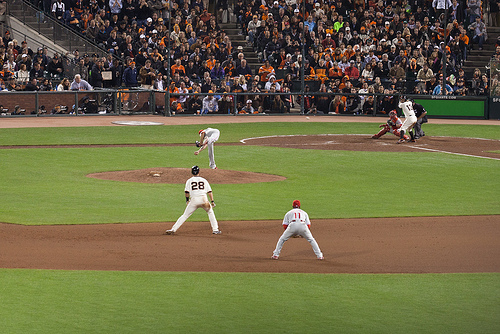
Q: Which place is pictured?
A: It is a field.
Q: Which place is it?
A: It is a field.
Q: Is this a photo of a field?
A: Yes, it is showing a field.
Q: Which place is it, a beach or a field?
A: It is a field.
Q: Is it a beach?
A: No, it is a field.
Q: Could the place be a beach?
A: No, it is a field.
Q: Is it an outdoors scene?
A: Yes, it is outdoors.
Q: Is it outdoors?
A: Yes, it is outdoors.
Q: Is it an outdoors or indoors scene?
A: It is outdoors.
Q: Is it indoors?
A: No, it is outdoors.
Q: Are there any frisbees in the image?
A: No, there are no frisbees.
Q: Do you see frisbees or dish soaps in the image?
A: No, there are no frisbees or dish soaps.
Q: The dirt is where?
A: The dirt is on the field.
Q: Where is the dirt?
A: The dirt is on the field.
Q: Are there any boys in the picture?
A: No, there are no boys.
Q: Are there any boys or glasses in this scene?
A: No, there are no boys or glasses.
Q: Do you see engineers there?
A: No, there are no engineers.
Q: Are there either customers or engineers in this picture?
A: No, there are no engineers or customers.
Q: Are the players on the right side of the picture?
A: Yes, the players are on the right of the image.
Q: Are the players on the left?
A: No, the players are on the right of the image.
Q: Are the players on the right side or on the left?
A: The players are on the right of the image.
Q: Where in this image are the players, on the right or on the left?
A: The players are on the right of the image.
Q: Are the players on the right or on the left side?
A: The players are on the right of the image.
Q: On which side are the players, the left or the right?
A: The players are on the right of the image.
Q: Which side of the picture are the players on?
A: The players are on the right of the image.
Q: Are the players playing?
A: Yes, the players are playing.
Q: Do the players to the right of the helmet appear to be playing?
A: Yes, the players are playing.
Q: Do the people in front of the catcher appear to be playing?
A: Yes, the players are playing.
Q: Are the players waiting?
A: No, the players are playing.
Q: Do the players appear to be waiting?
A: No, the players are playing.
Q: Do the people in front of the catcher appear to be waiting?
A: No, the players are playing.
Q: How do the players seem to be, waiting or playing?
A: The players are playing.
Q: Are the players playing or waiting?
A: The players are playing.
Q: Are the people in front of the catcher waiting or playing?
A: The players are playing.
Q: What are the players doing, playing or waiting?
A: The players are playing.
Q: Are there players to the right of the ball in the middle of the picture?
A: Yes, there are players to the right of the ball.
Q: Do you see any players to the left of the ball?
A: No, the players are to the right of the ball.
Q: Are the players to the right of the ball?
A: Yes, the players are to the right of the ball.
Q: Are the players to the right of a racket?
A: No, the players are to the right of the ball.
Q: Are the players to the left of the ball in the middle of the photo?
A: No, the players are to the right of the ball.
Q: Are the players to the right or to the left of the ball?
A: The players are to the right of the ball.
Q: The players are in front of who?
A: The players are in front of the catcher.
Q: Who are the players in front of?
A: The players are in front of the catcher.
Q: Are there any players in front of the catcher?
A: Yes, there are players in front of the catcher.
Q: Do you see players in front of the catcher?
A: Yes, there are players in front of the catcher.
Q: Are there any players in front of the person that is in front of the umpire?
A: Yes, there are players in front of the catcher.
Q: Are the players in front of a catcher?
A: Yes, the players are in front of a catcher.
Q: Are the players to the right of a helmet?
A: Yes, the players are to the right of a helmet.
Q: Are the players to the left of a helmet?
A: No, the players are to the right of a helmet.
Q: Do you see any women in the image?
A: No, there are no women.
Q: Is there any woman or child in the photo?
A: No, there are no women or children.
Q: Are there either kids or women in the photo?
A: No, there are no women or kids.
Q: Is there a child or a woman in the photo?
A: No, there are no women or children.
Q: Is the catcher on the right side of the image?
A: Yes, the catcher is on the right of the image.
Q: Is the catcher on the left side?
A: No, the catcher is on the right of the image.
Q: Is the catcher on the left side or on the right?
A: The catcher is on the right of the image.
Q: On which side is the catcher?
A: The catcher is on the right of the image.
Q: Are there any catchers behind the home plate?
A: Yes, there is a catcher behind the home plate.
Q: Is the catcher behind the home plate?
A: Yes, the catcher is behind the home plate.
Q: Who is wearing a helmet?
A: The catcher is wearing a helmet.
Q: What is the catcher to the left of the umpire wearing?
A: The catcher is wearing a helmet.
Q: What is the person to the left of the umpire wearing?
A: The catcher is wearing a helmet.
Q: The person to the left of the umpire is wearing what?
A: The catcher is wearing a helmet.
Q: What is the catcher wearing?
A: The catcher is wearing a helmet.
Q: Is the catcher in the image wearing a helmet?
A: Yes, the catcher is wearing a helmet.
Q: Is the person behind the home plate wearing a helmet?
A: Yes, the catcher is wearing a helmet.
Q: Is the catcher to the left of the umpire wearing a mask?
A: No, the catcher is wearing a helmet.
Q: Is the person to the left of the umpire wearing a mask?
A: No, the catcher is wearing a helmet.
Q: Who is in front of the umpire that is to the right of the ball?
A: The catcher is in front of the umpire.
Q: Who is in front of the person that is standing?
A: The catcher is in front of the umpire.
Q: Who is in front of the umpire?
A: The catcher is in front of the umpire.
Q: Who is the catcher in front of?
A: The catcher is in front of the umpire.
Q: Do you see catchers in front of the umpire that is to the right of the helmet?
A: Yes, there is a catcher in front of the umpire.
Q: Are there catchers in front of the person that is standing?
A: Yes, there is a catcher in front of the umpire.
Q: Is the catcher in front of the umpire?
A: Yes, the catcher is in front of the umpire.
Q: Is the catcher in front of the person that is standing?
A: Yes, the catcher is in front of the umpire.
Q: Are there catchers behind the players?
A: Yes, there is a catcher behind the players.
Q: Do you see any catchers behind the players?
A: Yes, there is a catcher behind the players.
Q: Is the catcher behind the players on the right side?
A: Yes, the catcher is behind the players.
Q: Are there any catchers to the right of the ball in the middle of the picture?
A: Yes, there is a catcher to the right of the ball.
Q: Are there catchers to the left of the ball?
A: No, the catcher is to the right of the ball.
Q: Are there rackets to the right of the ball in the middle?
A: No, there is a catcher to the right of the ball.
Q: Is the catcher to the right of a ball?
A: Yes, the catcher is to the right of a ball.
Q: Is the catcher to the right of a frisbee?
A: No, the catcher is to the right of a ball.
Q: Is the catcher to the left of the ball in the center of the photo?
A: No, the catcher is to the right of the ball.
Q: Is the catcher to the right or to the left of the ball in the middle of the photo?
A: The catcher is to the right of the ball.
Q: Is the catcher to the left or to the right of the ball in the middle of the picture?
A: The catcher is to the right of the ball.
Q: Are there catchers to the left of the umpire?
A: Yes, there is a catcher to the left of the umpire.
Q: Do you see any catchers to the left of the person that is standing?
A: Yes, there is a catcher to the left of the umpire.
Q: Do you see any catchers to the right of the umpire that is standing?
A: No, the catcher is to the left of the umpire.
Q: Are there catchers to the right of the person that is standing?
A: No, the catcher is to the left of the umpire.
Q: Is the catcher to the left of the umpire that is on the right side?
A: Yes, the catcher is to the left of the umpire.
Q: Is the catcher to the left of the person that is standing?
A: Yes, the catcher is to the left of the umpire.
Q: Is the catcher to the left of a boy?
A: No, the catcher is to the left of the umpire.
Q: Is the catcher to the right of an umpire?
A: No, the catcher is to the left of an umpire.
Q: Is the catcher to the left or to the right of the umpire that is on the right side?
A: The catcher is to the left of the umpire.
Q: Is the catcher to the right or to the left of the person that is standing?
A: The catcher is to the left of the umpire.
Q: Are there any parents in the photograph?
A: No, there are no parents.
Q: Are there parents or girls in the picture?
A: No, there are no parents or girls.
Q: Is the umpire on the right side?
A: Yes, the umpire is on the right of the image.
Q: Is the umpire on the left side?
A: No, the umpire is on the right of the image.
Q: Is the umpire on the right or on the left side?
A: The umpire is on the right of the image.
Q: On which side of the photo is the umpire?
A: The umpire is on the right of the image.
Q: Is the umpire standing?
A: Yes, the umpire is standing.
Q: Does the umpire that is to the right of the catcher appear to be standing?
A: Yes, the umpire is standing.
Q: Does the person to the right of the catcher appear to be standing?
A: Yes, the umpire is standing.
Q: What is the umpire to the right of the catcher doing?
A: The umpire is standing.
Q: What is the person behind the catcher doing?
A: The umpire is standing.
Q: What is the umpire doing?
A: The umpire is standing.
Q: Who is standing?
A: The umpire is standing.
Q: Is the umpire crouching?
A: No, the umpire is standing.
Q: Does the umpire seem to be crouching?
A: No, the umpire is standing.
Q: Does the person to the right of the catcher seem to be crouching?
A: No, the umpire is standing.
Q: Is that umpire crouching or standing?
A: The umpire is standing.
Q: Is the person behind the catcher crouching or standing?
A: The umpire is standing.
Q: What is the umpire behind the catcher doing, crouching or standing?
A: The umpire is standing.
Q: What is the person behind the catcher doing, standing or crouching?
A: The umpire is standing.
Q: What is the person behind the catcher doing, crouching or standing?
A: The umpire is standing.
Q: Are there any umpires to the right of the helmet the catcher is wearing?
A: Yes, there is an umpire to the right of the helmet.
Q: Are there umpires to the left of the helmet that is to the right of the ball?
A: No, the umpire is to the right of the helmet.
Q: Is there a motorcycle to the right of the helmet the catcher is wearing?
A: No, there is an umpire to the right of the helmet.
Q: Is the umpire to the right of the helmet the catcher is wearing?
A: Yes, the umpire is to the right of the helmet.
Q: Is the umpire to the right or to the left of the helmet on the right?
A: The umpire is to the right of the helmet.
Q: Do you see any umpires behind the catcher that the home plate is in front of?
A: Yes, there is an umpire behind the catcher.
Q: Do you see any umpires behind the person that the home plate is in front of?
A: Yes, there is an umpire behind the catcher.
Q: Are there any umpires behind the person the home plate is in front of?
A: Yes, there is an umpire behind the catcher.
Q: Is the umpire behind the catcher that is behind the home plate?
A: Yes, the umpire is behind the catcher.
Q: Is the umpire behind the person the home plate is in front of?
A: Yes, the umpire is behind the catcher.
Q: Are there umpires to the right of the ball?
A: Yes, there is an umpire to the right of the ball.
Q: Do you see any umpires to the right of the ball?
A: Yes, there is an umpire to the right of the ball.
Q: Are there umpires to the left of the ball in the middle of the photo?
A: No, the umpire is to the right of the ball.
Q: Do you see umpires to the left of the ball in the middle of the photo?
A: No, the umpire is to the right of the ball.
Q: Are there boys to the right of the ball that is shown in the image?
A: No, there is an umpire to the right of the ball.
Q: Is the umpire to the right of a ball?
A: Yes, the umpire is to the right of a ball.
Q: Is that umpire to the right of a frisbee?
A: No, the umpire is to the right of a ball.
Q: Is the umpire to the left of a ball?
A: No, the umpire is to the right of a ball.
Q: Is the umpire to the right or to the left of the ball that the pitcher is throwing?
A: The umpire is to the right of the ball.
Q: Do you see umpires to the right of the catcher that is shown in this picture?
A: Yes, there is an umpire to the right of the catcher.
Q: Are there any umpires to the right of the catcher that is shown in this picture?
A: Yes, there is an umpire to the right of the catcher.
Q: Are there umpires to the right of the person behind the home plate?
A: Yes, there is an umpire to the right of the catcher.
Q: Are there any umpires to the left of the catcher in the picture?
A: No, the umpire is to the right of the catcher.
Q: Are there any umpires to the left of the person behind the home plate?
A: No, the umpire is to the right of the catcher.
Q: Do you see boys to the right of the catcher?
A: No, there is an umpire to the right of the catcher.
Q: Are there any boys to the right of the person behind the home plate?
A: No, there is an umpire to the right of the catcher.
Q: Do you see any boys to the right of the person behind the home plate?
A: No, there is an umpire to the right of the catcher.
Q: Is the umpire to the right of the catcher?
A: Yes, the umpire is to the right of the catcher.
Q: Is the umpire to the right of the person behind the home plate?
A: Yes, the umpire is to the right of the catcher.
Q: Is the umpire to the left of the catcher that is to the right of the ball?
A: No, the umpire is to the right of the catcher.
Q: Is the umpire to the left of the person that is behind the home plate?
A: No, the umpire is to the right of the catcher.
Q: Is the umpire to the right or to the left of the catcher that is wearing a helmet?
A: The umpire is to the right of the catcher.